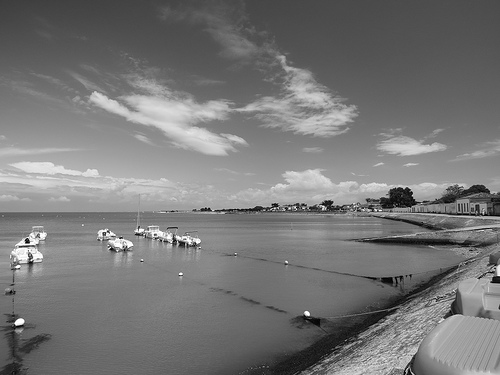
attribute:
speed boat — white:
[10, 243, 41, 263]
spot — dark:
[52, 271, 92, 281]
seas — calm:
[105, 247, 348, 356]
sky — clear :
[43, 32, 463, 201]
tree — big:
[372, 186, 427, 213]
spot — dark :
[316, 251, 396, 271]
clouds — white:
[77, 51, 451, 166]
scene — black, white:
[1, 0, 498, 374]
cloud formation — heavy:
[113, 67, 402, 190]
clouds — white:
[1, 0, 499, 212]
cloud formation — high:
[57, 50, 360, 162]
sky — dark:
[351, 29, 439, 102]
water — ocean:
[0, 213, 252, 257]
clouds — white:
[73, 44, 359, 157]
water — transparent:
[4, 198, 490, 372]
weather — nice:
[38, 34, 498, 206]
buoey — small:
[177, 272, 183, 276]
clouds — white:
[273, 167, 360, 194]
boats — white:
[9, 213, 208, 293]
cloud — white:
[373, 125, 449, 156]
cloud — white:
[228, 167, 472, 205]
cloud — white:
[73, 7, 356, 157]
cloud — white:
[1, 160, 186, 214]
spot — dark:
[363, 266, 407, 298]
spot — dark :
[291, 309, 368, 334]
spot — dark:
[209, 284, 226, 294]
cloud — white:
[376, 127, 447, 160]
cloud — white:
[195, 14, 361, 145]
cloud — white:
[8, 154, 98, 183]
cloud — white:
[375, 131, 448, 160]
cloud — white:
[271, 164, 358, 194]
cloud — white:
[85, 82, 249, 161]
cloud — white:
[6, 159, 103, 185]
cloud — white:
[381, 127, 444, 154]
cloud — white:
[3, 159, 104, 180]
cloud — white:
[275, 168, 355, 190]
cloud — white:
[89, 68, 245, 158]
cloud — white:
[240, 59, 361, 140]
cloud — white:
[88, 76, 248, 162]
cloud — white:
[8, 160, 98, 179]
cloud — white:
[371, 126, 448, 160]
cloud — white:
[238, 50, 365, 140]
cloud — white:
[273, 165, 365, 195]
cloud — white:
[86, 74, 246, 154]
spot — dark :
[304, 262, 339, 281]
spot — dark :
[221, 283, 270, 313]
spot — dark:
[238, 289, 265, 311]